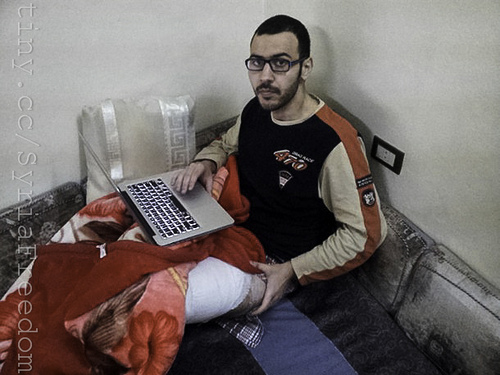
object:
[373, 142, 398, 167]
outlet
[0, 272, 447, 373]
bedspread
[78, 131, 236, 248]
laptop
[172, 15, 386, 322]
man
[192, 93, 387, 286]
shirt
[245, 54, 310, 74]
glasses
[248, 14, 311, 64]
hair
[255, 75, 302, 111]
beard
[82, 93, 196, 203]
cushion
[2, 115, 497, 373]
bed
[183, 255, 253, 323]
bandage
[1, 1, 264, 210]
wall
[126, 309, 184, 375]
flower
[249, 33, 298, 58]
forehead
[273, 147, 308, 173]
logo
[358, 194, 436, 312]
pillow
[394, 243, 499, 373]
pillow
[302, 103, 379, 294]
stripe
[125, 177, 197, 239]
keyboard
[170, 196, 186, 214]
spacebar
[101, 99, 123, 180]
strip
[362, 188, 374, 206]
patch